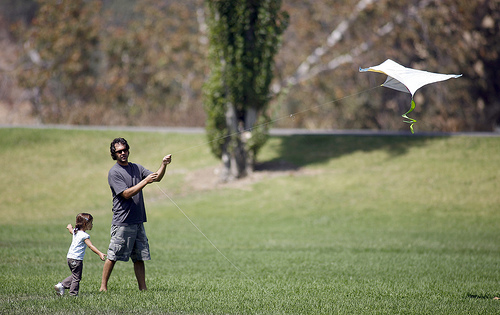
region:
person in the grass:
[102, 136, 160, 290]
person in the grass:
[51, 195, 94, 292]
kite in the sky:
[361, 42, 463, 135]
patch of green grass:
[332, 220, 366, 255]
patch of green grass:
[257, 279, 284, 310]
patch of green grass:
[339, 265, 366, 295]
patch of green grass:
[168, 268, 200, 305]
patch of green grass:
[248, 220, 275, 247]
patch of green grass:
[208, 228, 238, 255]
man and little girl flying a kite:
[3, 0, 494, 306]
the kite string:
[148, 80, 398, 161]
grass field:
[3, 130, 493, 306]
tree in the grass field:
[206, 2, 272, 175]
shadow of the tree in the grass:
[242, 136, 452, 177]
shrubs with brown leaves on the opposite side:
[0, 5, 490, 116]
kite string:
[143, 162, 314, 304]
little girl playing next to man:
[47, 205, 113, 286]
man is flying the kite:
[103, 59, 461, 287]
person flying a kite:
[111, 130, 166, 289]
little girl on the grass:
[36, 201, 103, 302]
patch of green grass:
[221, 283, 256, 310]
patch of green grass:
[293, 281, 323, 309]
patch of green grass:
[343, 274, 373, 306]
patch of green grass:
[372, 272, 417, 305]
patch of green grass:
[300, 238, 337, 264]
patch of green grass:
[392, 230, 425, 257]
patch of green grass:
[238, 251, 264, 273]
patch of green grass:
[175, 274, 198, 309]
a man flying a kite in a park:
[98, 57, 462, 292]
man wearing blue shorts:
[108, 222, 150, 261]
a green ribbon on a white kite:
[404, 94, 416, 134]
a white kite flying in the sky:
[356, 58, 463, 96]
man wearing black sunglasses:
[111, 145, 132, 154]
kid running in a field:
[53, 212, 105, 296]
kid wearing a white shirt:
[68, 230, 89, 257]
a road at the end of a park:
[4, 120, 499, 135]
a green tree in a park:
[198, 2, 288, 180]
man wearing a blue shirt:
[108, 165, 149, 222]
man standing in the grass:
[95, 135, 185, 290]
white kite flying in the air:
[355, 51, 470, 136]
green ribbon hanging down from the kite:
[396, 95, 417, 130]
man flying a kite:
[86, 51, 471, 311]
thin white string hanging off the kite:
[155, 70, 405, 180]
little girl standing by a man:
[45, 131, 170, 311]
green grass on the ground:
[0, 127, 496, 307]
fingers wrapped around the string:
[160, 151, 176, 166]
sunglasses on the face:
[113, 145, 130, 154]